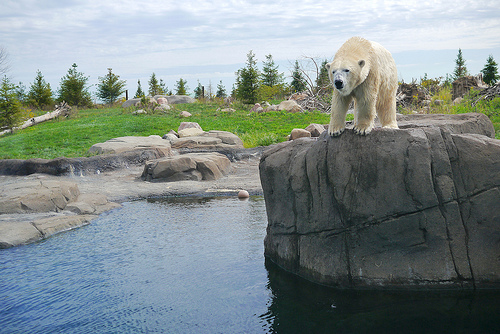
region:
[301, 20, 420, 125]
this is a bear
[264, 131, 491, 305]
this is a rock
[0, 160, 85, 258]
this is a rock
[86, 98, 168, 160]
this is a rock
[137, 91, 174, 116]
this is a rock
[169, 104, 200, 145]
this is a rock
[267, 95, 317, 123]
this is a rock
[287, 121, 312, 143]
this is a rock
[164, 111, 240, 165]
this is a rock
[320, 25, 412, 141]
white adult polar bear on gray rock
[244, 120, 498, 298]
large gray rock in water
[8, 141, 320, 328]
blue water with gray rocks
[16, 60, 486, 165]
green grassy land mass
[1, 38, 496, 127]
row pf green evergreen trees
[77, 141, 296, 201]
water breaking over gray rocks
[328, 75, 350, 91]
black nose on white bear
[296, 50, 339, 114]
dead bare tree branches near trees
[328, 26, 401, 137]
polar bear standing on all fours with head hunched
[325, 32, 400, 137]
White polar bear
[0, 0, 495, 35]
Overcast gray sky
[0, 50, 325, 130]
Small coniferous trees in polar bear enclosure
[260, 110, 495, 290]
Manufactured rock with horizontal and vertical cracks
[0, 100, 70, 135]
Log lying on ground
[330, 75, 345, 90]
Polar bear nose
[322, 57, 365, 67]
Polar bear ears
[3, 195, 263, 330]
Polar bear swimming pond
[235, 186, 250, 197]
Ball on beach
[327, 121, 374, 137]
Polar bear claws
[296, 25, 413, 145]
the polar bear is on the rock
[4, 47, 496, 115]
several trees are in the background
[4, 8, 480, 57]
the sky if full of white fluffy clouds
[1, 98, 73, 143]
a log lay on the ground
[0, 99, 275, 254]
rocks lay in the water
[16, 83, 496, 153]
green grass covers this portion of the land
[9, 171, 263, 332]
this area is a body of water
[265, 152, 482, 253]
the rock has several cracks in it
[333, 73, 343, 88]
the polar bear has a black nose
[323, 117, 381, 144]
the bears front paws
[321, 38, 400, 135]
large furry white polar bear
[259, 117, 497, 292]
large grey rock cliff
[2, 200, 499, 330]
large open water pool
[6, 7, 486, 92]
The cloudy sky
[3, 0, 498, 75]
A cloudy sky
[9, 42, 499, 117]
the forest of trees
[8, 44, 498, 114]
A forest of trees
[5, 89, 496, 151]
The grassy meadow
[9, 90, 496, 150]
A grassy meadow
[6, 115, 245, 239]
The gray rocks in the water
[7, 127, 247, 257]
A set of rocks in the water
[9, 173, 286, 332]
The body of water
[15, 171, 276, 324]
A body of water